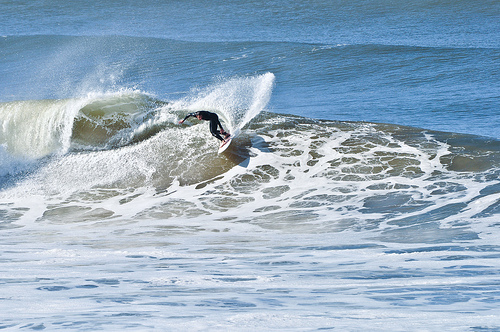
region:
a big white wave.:
[0, 75, 161, 175]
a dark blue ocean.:
[308, 4, 498, 111]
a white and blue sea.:
[281, 74, 488, 262]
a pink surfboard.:
[213, 136, 238, 161]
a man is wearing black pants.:
[208, 125, 222, 140]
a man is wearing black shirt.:
[205, 107, 222, 122]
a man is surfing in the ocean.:
[168, 89, 253, 184]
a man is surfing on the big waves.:
[1, 80, 255, 177]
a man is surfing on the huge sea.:
[126, 67, 285, 194]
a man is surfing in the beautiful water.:
[0, 26, 497, 327]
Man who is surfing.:
[162, 100, 259, 164]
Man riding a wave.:
[162, 78, 272, 165]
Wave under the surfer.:
[163, 66, 417, 229]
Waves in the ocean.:
[41, 80, 481, 243]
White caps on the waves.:
[22, 86, 142, 159]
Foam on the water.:
[148, 148, 323, 227]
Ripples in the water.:
[55, 249, 234, 329]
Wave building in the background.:
[284, 10, 479, 128]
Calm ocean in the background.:
[311, 5, 497, 63]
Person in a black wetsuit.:
[171, 103, 246, 159]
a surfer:
[182, 111, 231, 142]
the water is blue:
[46, 217, 479, 330]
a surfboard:
[217, 141, 232, 156]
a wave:
[10, 98, 108, 150]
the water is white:
[266, 148, 389, 204]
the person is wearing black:
[169, 111, 239, 154]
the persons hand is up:
[178, 114, 228, 141]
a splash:
[217, 83, 267, 119]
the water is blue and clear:
[280, 4, 496, 110]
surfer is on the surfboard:
[176, 110, 238, 150]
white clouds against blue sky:
[0, 0, 61, 55]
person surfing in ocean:
[170, 99, 258, 184]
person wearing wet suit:
[192, 106, 240, 164]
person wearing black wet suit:
[186, 96, 227, 166]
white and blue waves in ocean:
[19, 205, 131, 302]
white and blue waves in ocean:
[183, 218, 294, 299]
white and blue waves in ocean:
[293, 196, 407, 290]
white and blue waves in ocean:
[382, 95, 487, 207]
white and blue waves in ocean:
[300, 96, 381, 197]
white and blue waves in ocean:
[49, 68, 107, 152]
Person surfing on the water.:
[179, 97, 237, 167]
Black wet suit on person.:
[177, 101, 233, 152]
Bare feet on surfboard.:
[212, 125, 232, 153]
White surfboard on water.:
[210, 126, 234, 158]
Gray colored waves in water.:
[357, 113, 498, 186]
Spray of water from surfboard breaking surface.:
[191, 93, 281, 148]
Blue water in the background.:
[379, 93, 498, 129]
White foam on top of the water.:
[265, 241, 360, 302]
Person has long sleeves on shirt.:
[178, 104, 230, 147]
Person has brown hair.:
[185, 103, 282, 158]